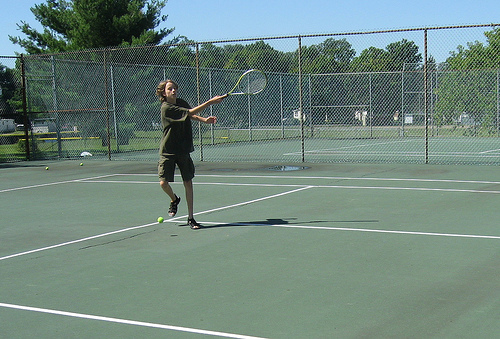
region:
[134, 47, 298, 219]
boy is playing tennis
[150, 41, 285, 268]
boy holding a racket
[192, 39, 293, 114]
boy holding a racket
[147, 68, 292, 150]
boy holding a racket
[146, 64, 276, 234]
a person playing tennis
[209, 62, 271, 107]
a tennis racket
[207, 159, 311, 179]
a puddle of water on the tennis court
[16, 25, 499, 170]
a chain link fence dividing the tennis courts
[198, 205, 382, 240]
a shadow cast on the tennis court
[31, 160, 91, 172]
two tennis balls on the ground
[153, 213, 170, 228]
a tennis ball that the player missed hitting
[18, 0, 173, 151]
a large tree behind the tennis courts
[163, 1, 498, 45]
a clear blue sky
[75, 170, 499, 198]
white lines painted on the tennis court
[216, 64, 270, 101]
A white tennis racket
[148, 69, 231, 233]
A boy playing tennis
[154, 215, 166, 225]
A green tennis ball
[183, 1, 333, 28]
A clear blue sky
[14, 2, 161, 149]
A tall, evergreen tree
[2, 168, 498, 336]
A green and white tennis court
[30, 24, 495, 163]
A chain link metal fence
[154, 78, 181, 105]
A person's face and hair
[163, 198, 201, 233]
A pair of tennis shoes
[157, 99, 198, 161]
A dark green t-shirt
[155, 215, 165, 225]
Yellow tennis ball on court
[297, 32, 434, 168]
Wire fence on tennis court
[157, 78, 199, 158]
Woman wearing dark green shirt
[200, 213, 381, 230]
Shadow on tennis court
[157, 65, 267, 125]
Human holding tennis racket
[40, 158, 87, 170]
Two tennis balls on tennis court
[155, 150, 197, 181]
Dark green shorts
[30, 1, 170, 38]
Top of a dark green tree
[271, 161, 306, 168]
Puddle of water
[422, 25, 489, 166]
Chain link fence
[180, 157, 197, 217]
a leg of a person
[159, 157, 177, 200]
the leg of a person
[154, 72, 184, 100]
the head of a person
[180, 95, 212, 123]
the arms of a person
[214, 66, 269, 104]
a hand holding a tennis racket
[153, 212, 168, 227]
a tennis ball on the ground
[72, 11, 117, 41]
the leaves of a tree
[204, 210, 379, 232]
a shadow of a tennis player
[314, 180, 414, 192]
the white line on a tennis court